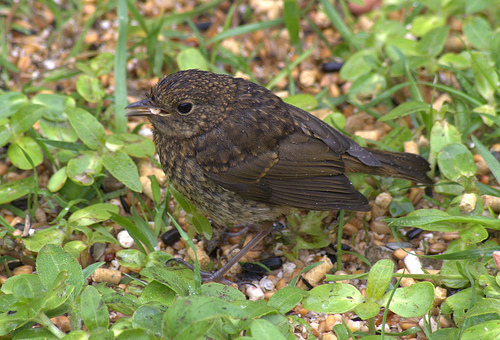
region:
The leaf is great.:
[326, 44, 457, 106]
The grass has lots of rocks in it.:
[183, 226, 417, 306]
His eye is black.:
[170, 97, 196, 124]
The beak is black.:
[118, 92, 177, 139]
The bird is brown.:
[140, 67, 397, 235]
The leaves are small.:
[28, 92, 160, 227]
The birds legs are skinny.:
[160, 211, 310, 297]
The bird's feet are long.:
[153, 249, 235, 306]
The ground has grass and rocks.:
[14, 3, 496, 329]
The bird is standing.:
[67, 68, 422, 293]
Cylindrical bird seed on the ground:
[86, 265, 124, 285]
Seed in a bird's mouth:
[146, 105, 161, 114]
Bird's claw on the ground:
[154, 250, 261, 292]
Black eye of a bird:
[178, 97, 198, 117]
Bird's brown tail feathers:
[357, 140, 434, 185]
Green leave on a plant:
[296, 280, 363, 317]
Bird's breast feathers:
[151, 145, 281, 235]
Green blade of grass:
[111, 4, 134, 134]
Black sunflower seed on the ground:
[238, 255, 290, 275]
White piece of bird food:
[401, 249, 426, 276]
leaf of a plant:
[204, 298, 227, 310]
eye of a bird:
[176, 95, 198, 111]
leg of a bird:
[254, 220, 264, 243]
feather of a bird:
[196, 164, 212, 179]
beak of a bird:
[138, 102, 163, 117]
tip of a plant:
[95, 143, 106, 148]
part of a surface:
[325, 256, 348, 258]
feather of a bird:
[256, 149, 277, 179]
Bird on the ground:
[93, 43, 405, 307]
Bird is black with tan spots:
[162, 60, 342, 300]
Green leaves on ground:
[40, 86, 210, 316]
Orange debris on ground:
[239, 250, 388, 330]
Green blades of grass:
[104, 19, 131, 143]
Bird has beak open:
[125, 55, 180, 140]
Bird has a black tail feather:
[238, 117, 448, 293]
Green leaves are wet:
[412, 105, 487, 220]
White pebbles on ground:
[87, 215, 137, 251]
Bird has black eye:
[164, 83, 226, 130]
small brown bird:
[101, 47, 453, 272]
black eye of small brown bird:
[165, 85, 201, 124]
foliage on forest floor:
[2, 78, 119, 336]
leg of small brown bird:
[155, 202, 293, 302]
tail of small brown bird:
[338, 115, 444, 201]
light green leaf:
[61, 95, 111, 156]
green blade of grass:
[102, 1, 132, 135]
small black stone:
[315, 50, 347, 80]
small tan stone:
[292, 250, 340, 291]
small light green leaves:
[27, 235, 123, 338]